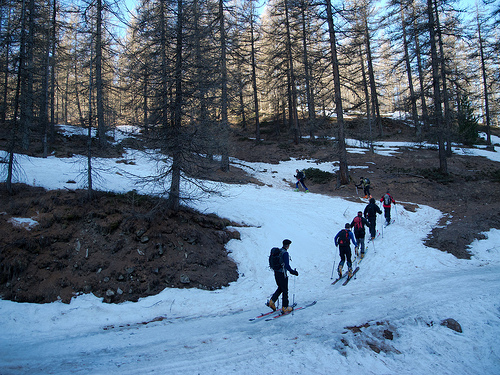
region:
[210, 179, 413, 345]
people walking in the snow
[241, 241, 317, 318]
man in the back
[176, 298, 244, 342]
white snow on the ground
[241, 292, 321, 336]
skis beneath the man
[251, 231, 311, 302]
man with a backpack on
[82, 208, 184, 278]
brown dirt below tree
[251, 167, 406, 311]
people walking up the hill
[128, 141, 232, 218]
tree with no leaves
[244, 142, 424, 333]
six people walking in a line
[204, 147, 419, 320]
group of people wearing skis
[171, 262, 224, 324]
part of a ground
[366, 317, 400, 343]
part of some stones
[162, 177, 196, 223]
stem of a tree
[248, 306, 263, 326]
part of a slider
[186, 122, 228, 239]
part of some branches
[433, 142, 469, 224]
part of a ground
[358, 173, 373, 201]
Person skiing up the hill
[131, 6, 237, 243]
A tree with no leaves.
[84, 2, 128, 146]
A tree with no leaves.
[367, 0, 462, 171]
A tree with no leaves.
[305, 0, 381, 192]
A tree with no leaves.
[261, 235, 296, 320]
a man in the snow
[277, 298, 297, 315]
a brown boot on the man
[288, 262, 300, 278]
a black glove on the man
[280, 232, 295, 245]
a black hat on the man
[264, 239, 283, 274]
a backpack on the man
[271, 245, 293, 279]
a coat on the man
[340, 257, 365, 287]
a ski on the snow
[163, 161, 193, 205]
the trunk of a tree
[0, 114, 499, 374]
white snow on the ground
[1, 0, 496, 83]
a clear blue sky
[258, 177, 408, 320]
a line of skiiers going along the hill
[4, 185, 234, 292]
some dirt to the left of the snow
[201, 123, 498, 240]
patches of dirt on the right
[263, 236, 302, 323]
the skiier at the end of the line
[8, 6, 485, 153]
a group of leafless trees in the forest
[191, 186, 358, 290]
more snow on the ground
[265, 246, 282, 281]
the backpack on the last man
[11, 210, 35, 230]
some snow on the dirt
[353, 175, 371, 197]
the first person in line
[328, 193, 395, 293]
a straight line of skiiers